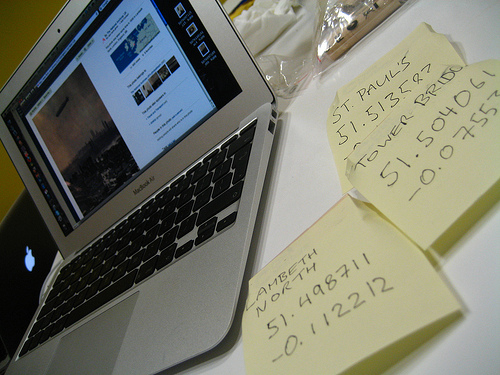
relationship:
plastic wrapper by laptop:
[255, 0, 410, 101] [0, 0, 278, 374]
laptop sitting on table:
[0, 0, 278, 374] [154, 0, 500, 374]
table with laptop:
[154, 0, 500, 374] [0, 0, 278, 374]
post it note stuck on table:
[239, 193, 462, 374] [154, 0, 500, 374]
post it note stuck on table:
[349, 60, 499, 252] [154, 0, 500, 374]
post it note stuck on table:
[328, 21, 464, 191] [154, 0, 500, 374]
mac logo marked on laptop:
[23, 245, 37, 272] [0, 189, 58, 363]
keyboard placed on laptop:
[18, 116, 258, 356] [0, 0, 278, 374]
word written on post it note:
[245, 245, 319, 317] [239, 193, 462, 374]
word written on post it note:
[349, 65, 498, 201] [349, 60, 499, 252]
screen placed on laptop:
[1, 0, 244, 235] [0, 0, 278, 374]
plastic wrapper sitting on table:
[255, 0, 410, 101] [154, 0, 500, 374]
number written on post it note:
[265, 313, 280, 342] [239, 193, 462, 374]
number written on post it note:
[284, 332, 298, 356] [239, 193, 462, 374]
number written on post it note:
[299, 293, 313, 306] [239, 193, 462, 374]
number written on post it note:
[311, 283, 325, 296] [239, 193, 462, 374]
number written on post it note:
[325, 273, 338, 292] [239, 193, 462, 374]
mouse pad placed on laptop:
[48, 289, 138, 374] [0, 0, 278, 374]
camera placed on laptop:
[55, 27, 62, 35] [0, 0, 278, 374]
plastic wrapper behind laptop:
[255, 0, 410, 101] [0, 0, 278, 374]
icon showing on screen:
[57, 215, 64, 221] [1, 0, 244, 235]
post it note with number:
[239, 193, 462, 374] [265, 313, 280, 342]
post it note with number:
[239, 193, 462, 374] [299, 293, 313, 306]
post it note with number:
[239, 193, 462, 374] [311, 283, 325, 296]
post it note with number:
[239, 193, 462, 374] [325, 273, 338, 292]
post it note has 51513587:
[328, 21, 464, 191] [335, 60, 432, 149]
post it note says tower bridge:
[349, 60, 499, 252] [354, 63, 468, 172]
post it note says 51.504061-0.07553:
[349, 60, 499, 252] [349, 65, 498, 201]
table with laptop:
[154, 0, 500, 374] [0, 189, 58, 363]